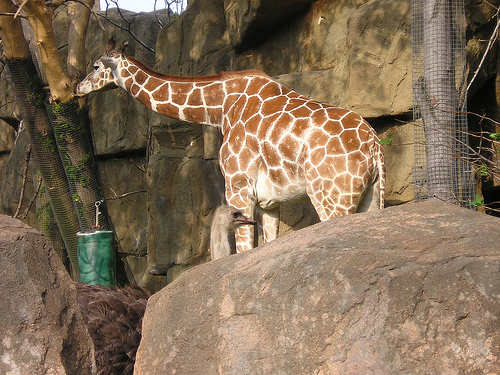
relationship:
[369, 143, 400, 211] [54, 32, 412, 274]
tail behind giraffe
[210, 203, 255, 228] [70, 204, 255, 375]
head on emu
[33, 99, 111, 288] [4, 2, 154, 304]
moss on tree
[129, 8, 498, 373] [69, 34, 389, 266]
rocks behind giraffe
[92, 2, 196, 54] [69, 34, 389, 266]
tree above giraffe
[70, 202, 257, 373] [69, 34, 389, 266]
emu in front of giraffe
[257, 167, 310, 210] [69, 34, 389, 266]
belly on giraffe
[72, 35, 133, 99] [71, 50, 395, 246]
head on giraffe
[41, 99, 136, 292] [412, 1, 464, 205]
trunk of tree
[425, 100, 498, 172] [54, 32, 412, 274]
branches behind giraffe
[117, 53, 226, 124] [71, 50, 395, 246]
neck of giraffe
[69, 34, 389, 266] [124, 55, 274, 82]
giraffe has mane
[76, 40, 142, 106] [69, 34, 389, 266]
head of giraffe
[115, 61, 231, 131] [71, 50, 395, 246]
neck of giraffe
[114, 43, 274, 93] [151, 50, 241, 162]
mane over neck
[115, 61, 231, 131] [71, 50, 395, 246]
neck down on giraffe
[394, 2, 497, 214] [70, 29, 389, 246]
fence behind giraffe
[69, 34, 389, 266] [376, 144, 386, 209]
giraffe has tail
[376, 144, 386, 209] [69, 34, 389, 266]
tail on giraffe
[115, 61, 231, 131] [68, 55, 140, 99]
neck on giraffe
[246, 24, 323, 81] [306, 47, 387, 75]
shadow on rock